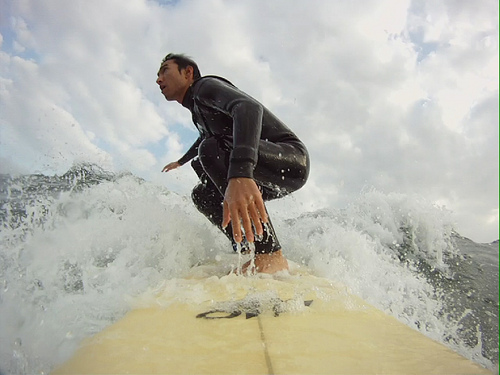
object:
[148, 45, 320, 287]
surfer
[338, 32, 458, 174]
cloud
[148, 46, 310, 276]
surfer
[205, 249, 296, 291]
barefeet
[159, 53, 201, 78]
black hair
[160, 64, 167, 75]
eyes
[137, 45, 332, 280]
person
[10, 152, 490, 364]
water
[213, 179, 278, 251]
hand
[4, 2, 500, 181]
cloudy sky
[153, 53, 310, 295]
surfer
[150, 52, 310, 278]
wetsuit man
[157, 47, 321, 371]
surfer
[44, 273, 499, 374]
board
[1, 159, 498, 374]
waves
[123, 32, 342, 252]
man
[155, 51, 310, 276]
rider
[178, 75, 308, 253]
wetsuit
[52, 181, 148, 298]
white tiles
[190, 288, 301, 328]
writing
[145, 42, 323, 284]
man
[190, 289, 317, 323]
text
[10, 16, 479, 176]
sky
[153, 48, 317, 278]
man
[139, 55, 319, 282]
man